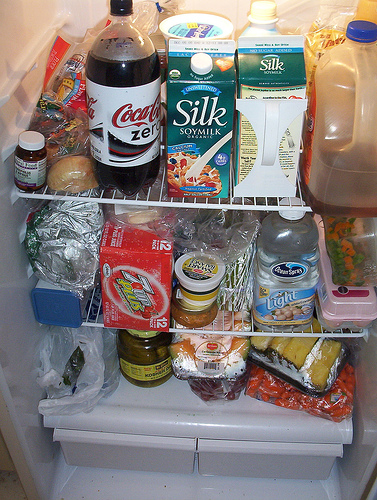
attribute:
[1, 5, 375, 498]
fridge — white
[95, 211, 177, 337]
7 up box — red, 12 pack, twelve pack, for soda cans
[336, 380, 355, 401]
baby carrot — orange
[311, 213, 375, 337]
egg case — white, pink, styrofoam, for a dozen eggs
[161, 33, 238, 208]
soy milk carton — silk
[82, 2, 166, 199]
coca cola bottle — two liter, plastic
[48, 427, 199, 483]
drawer — white, crisper drawer, vegetable drawer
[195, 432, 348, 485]
drawer — white, crisper drawer, vegetable drawer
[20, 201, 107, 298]
foil bag — silver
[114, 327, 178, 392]
pickle — green, kosher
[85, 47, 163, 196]
coca cola — zero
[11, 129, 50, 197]
bottle — pill bottle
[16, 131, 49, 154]
cap — white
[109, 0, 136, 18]
cap — black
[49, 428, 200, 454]
handle — white, plastic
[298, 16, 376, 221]
jug — plastic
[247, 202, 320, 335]
bottle — plastic, juice bottle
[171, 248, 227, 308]
margarine container — yellow, white